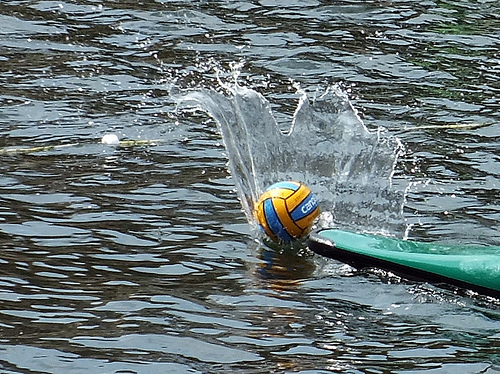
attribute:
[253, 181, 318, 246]
ball — yellow and blue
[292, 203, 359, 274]
tip — black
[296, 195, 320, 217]
letters — white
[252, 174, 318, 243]
ball — blue, yellow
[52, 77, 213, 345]
water — murky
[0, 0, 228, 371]
murky water — rippled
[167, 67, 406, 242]
splash — big, water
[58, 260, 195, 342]
water — murky, rippled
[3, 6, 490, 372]
water — murky, dark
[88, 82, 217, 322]
water — calm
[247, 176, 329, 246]
ball — floating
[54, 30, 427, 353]
water — splash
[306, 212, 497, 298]
object — green